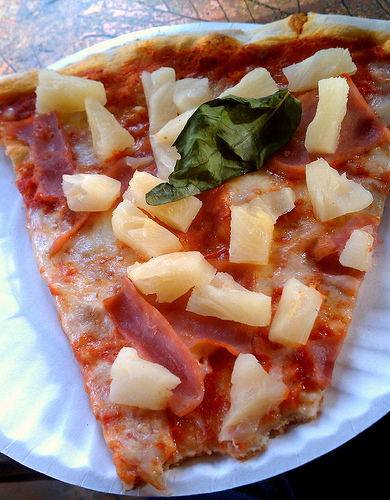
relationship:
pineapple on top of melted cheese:
[42, 59, 371, 430] [0, 12, 390, 492]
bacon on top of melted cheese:
[26, 105, 352, 423] [0, 12, 390, 492]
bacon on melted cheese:
[26, 105, 352, 423] [0, 12, 390, 492]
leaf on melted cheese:
[146, 78, 290, 195] [0, 12, 390, 492]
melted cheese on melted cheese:
[0, 12, 390, 492] [0, 12, 390, 492]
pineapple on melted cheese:
[42, 59, 371, 430] [0, 12, 390, 492]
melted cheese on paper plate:
[0, 12, 390, 492] [2, 146, 388, 499]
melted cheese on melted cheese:
[16, 67, 374, 468] [0, 12, 390, 492]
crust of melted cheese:
[1, 0, 388, 101] [0, 12, 390, 492]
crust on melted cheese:
[1, 0, 388, 101] [0, 12, 390, 492]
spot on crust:
[286, 7, 313, 38] [1, 0, 388, 101]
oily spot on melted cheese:
[274, 222, 308, 256] [16, 67, 374, 468]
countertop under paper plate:
[3, 5, 388, 83] [2, 146, 388, 499]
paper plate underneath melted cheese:
[2, 146, 388, 499] [0, 12, 390, 492]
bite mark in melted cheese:
[122, 407, 334, 499] [0, 12, 390, 492]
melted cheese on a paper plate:
[0, 12, 390, 492] [2, 146, 388, 499]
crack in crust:
[296, 9, 312, 34] [1, 0, 388, 101]